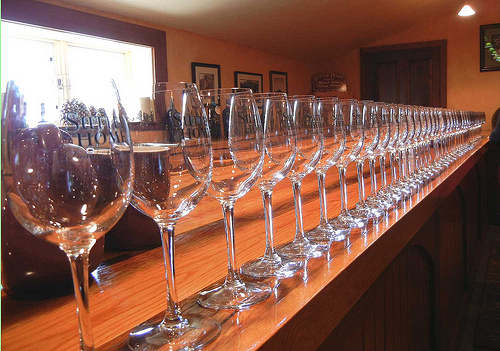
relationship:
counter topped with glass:
[13, 111, 484, 349] [252, 88, 307, 294]